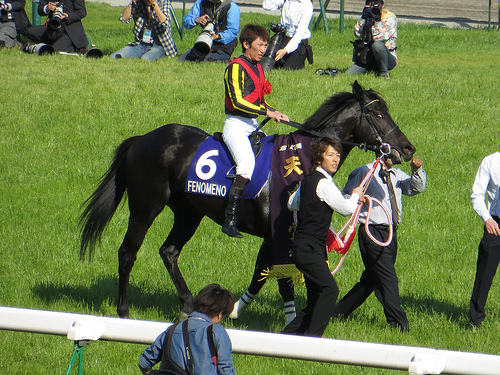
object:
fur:
[128, 124, 175, 181]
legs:
[113, 193, 203, 318]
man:
[330, 150, 421, 339]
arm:
[225, 60, 284, 122]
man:
[218, 21, 288, 245]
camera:
[355, 3, 383, 28]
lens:
[369, 5, 381, 18]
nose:
[380, 120, 423, 158]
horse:
[75, 80, 422, 322]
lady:
[224, 32, 375, 261]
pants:
[210, 96, 288, 240]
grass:
[19, 285, 489, 374]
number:
[195, 149, 220, 180]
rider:
[221, 27, 286, 233]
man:
[463, 137, 498, 329]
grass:
[16, 83, 124, 339]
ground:
[48, 31, 483, 336]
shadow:
[214, 272, 420, 322]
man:
[141, 277, 241, 373]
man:
[284, 137, 368, 337]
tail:
[78, 142, 123, 267]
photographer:
[312, 0, 402, 83]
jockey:
[217, 18, 274, 245]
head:
[323, 80, 420, 184]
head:
[306, 131, 350, 178]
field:
[2, 1, 497, 372]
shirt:
[135, 308, 237, 373]